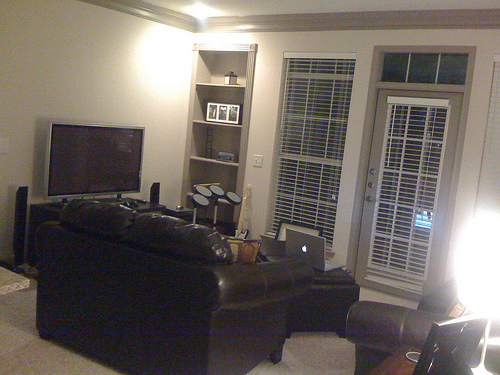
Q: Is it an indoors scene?
A: Yes, it is indoors.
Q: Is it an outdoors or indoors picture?
A: It is indoors.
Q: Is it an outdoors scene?
A: No, it is indoors.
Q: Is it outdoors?
A: No, it is indoors.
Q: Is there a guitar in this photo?
A: Yes, there is a guitar.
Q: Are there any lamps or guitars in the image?
A: Yes, there is a guitar.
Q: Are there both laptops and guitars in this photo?
A: Yes, there are both a guitar and a laptop.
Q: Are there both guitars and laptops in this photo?
A: Yes, there are both a guitar and a laptop.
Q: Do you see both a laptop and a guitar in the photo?
A: Yes, there are both a guitar and a laptop.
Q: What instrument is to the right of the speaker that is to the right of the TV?
A: The instrument is a guitar.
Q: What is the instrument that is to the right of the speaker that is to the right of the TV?
A: The instrument is a guitar.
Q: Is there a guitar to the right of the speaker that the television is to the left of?
A: Yes, there is a guitar to the right of the speaker.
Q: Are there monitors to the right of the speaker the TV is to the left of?
A: No, there is a guitar to the right of the speaker.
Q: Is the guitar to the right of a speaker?
A: Yes, the guitar is to the right of a speaker.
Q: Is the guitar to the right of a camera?
A: No, the guitar is to the right of a speaker.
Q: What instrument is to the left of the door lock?
A: The instrument is a guitar.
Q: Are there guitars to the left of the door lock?
A: Yes, there is a guitar to the left of the lock.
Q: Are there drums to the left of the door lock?
A: No, there is a guitar to the left of the lock.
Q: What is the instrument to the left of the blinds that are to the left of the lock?
A: The instrument is a guitar.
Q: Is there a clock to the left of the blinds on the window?
A: No, there is a guitar to the left of the blinds.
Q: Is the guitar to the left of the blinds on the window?
A: Yes, the guitar is to the left of the blinds.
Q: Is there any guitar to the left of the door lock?
A: Yes, there is a guitar to the left of the lock.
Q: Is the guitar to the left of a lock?
A: Yes, the guitar is to the left of a lock.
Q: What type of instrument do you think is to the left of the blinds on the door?
A: The instrument is a guitar.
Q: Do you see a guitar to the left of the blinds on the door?
A: Yes, there is a guitar to the left of the blinds.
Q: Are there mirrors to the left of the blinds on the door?
A: No, there is a guitar to the left of the blinds.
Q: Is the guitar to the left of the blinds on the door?
A: Yes, the guitar is to the left of the blinds.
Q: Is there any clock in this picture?
A: No, there are no clocks.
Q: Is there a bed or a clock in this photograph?
A: No, there are no clocks or beds.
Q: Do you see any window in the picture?
A: Yes, there are windows.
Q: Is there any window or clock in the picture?
A: Yes, there are windows.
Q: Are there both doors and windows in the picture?
A: Yes, there are both windows and a door.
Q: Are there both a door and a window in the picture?
A: Yes, there are both a window and a door.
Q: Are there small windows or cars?
A: Yes, there are small windows.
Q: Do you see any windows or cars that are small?
A: Yes, the windows are small.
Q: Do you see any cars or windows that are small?
A: Yes, the windows are small.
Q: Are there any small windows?
A: Yes, there are small windows.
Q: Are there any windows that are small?
A: Yes, there are windows that are small.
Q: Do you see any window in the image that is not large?
A: Yes, there are small windows.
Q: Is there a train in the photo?
A: No, there are no trains.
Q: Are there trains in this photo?
A: No, there are no trains.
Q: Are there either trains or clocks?
A: No, there are no trains or clocks.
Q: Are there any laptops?
A: Yes, there is a laptop.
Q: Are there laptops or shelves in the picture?
A: Yes, there is a laptop.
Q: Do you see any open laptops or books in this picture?
A: Yes, there is an open laptop.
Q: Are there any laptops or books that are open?
A: Yes, the laptop is open.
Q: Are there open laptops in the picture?
A: Yes, there is an open laptop.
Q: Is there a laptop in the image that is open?
A: Yes, there is a laptop that is open.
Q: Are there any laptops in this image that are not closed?
A: Yes, there is a open laptop.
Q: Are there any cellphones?
A: No, there are no cellphones.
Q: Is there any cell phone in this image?
A: No, there are no cell phones.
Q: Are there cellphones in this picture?
A: No, there are no cellphones.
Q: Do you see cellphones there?
A: No, there are no cellphones.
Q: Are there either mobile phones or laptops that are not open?
A: No, there is a laptop but it is open.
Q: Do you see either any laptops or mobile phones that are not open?
A: No, there is a laptop but it is open.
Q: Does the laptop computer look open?
A: Yes, the laptop computer is open.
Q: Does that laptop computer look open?
A: Yes, the laptop computer is open.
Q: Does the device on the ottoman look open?
A: Yes, the laptop computer is open.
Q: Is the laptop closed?
A: No, the laptop is open.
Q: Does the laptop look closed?
A: No, the laptop is open.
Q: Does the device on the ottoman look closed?
A: No, the laptop is open.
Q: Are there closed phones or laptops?
A: No, there is a laptop but it is open.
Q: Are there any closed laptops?
A: No, there is a laptop but it is open.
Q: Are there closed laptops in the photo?
A: No, there is a laptop but it is open.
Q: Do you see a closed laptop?
A: No, there is a laptop but it is open.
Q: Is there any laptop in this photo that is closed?
A: No, there is a laptop but it is open.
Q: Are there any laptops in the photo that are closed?
A: No, there is a laptop but it is open.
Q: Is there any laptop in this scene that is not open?
A: No, there is a laptop but it is open.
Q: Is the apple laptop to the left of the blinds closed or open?
A: The laptop is open.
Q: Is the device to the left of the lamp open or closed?
A: The laptop is open.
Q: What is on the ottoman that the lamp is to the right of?
A: The laptop is on the ottoman.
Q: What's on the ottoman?
A: The laptop is on the ottoman.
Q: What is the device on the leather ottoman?
A: The device is a laptop.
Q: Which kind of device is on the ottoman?
A: The device is a laptop.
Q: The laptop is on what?
A: The laptop is on the ottoman.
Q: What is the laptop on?
A: The laptop is on the ottoman.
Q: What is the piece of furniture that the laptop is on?
A: The piece of furniture is an ottoman.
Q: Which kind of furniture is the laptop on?
A: The laptop is on the ottoman.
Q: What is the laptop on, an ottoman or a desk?
A: The laptop is on an ottoman.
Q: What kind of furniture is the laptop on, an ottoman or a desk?
A: The laptop is on an ottoman.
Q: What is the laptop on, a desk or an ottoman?
A: The laptop is on an ottoman.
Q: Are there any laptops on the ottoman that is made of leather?
A: Yes, there is a laptop on the ottoman.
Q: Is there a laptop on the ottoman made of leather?
A: Yes, there is a laptop on the ottoman.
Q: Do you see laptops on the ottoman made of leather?
A: Yes, there is a laptop on the ottoman.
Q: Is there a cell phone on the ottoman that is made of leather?
A: No, there is a laptop on the ottoman.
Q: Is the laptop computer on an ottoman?
A: Yes, the laptop computer is on an ottoman.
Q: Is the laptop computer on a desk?
A: No, the laptop computer is on an ottoman.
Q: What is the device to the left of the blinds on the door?
A: The device is a laptop.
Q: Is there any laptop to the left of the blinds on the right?
A: Yes, there is a laptop to the left of the blinds.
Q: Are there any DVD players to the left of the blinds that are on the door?
A: No, there is a laptop to the left of the blinds.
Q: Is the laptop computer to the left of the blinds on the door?
A: Yes, the laptop computer is to the left of the blinds.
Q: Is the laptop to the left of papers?
A: No, the laptop is to the left of the blinds.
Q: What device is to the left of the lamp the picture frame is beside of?
A: The device is a laptop.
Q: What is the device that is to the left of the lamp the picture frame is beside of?
A: The device is a laptop.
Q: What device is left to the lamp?
A: The device is a laptop.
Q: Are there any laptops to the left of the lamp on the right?
A: Yes, there is a laptop to the left of the lamp.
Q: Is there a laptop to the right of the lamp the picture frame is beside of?
A: No, the laptop is to the left of the lamp.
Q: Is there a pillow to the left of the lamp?
A: No, there is a laptop to the left of the lamp.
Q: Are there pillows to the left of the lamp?
A: No, there is a laptop to the left of the lamp.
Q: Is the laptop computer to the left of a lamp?
A: Yes, the laptop computer is to the left of a lamp.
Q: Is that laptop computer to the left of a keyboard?
A: No, the laptop computer is to the left of a lamp.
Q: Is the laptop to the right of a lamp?
A: No, the laptop is to the left of a lamp.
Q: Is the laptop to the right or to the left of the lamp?
A: The laptop is to the left of the lamp.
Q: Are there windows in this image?
A: Yes, there is a window.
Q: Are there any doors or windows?
A: Yes, there is a window.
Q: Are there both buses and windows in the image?
A: No, there is a window but no buses.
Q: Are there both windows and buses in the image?
A: No, there is a window but no buses.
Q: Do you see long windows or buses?
A: Yes, there is a long window.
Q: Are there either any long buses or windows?
A: Yes, there is a long window.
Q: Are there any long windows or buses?
A: Yes, there is a long window.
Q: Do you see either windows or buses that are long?
A: Yes, the window is long.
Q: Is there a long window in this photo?
A: Yes, there is a long window.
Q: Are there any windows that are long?
A: Yes, there is a window that is long.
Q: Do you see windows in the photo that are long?
A: Yes, there is a window that is long.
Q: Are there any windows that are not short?
A: Yes, there is a long window.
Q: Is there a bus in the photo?
A: No, there are no buses.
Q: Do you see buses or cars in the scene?
A: No, there are no buses or cars.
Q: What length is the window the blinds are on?
A: The window is long.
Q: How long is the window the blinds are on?
A: The window is long.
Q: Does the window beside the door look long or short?
A: The window is long.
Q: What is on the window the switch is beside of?
A: The blinds are on the window.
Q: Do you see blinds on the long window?
A: Yes, there are blinds on the window.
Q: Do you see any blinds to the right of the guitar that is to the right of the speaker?
A: Yes, there are blinds to the right of the guitar.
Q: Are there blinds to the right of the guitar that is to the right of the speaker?
A: Yes, there are blinds to the right of the guitar.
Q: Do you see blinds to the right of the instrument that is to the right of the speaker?
A: Yes, there are blinds to the right of the guitar.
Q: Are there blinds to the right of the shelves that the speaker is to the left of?
A: Yes, there are blinds to the right of the shelves.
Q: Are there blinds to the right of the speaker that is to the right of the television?
A: Yes, there are blinds to the right of the speaker.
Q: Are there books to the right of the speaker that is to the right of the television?
A: No, there are blinds to the right of the speaker.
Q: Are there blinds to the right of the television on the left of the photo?
A: Yes, there are blinds to the right of the TV.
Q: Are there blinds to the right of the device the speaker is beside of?
A: Yes, there are blinds to the right of the TV.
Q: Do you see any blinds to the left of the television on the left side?
A: No, the blinds are to the right of the TV.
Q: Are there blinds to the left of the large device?
A: No, the blinds are to the right of the TV.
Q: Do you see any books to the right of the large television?
A: No, there are blinds to the right of the TV.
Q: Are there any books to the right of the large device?
A: No, there are blinds to the right of the TV.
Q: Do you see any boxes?
A: No, there are no boxes.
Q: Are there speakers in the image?
A: Yes, there is a speaker.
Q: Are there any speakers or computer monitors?
A: Yes, there is a speaker.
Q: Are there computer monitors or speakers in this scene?
A: Yes, there is a speaker.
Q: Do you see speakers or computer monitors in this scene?
A: Yes, there is a speaker.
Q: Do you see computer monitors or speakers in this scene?
A: Yes, there is a speaker.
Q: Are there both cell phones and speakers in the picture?
A: No, there is a speaker but no cell phones.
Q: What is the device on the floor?
A: The device is a speaker.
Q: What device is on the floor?
A: The device is a speaker.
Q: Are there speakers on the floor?
A: Yes, there is a speaker on the floor.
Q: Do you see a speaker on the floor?
A: Yes, there is a speaker on the floor.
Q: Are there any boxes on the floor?
A: No, there is a speaker on the floor.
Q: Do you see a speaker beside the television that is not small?
A: Yes, there is a speaker beside the television.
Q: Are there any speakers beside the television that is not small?
A: Yes, there is a speaker beside the television.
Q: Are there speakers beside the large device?
A: Yes, there is a speaker beside the television.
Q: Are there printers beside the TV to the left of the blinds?
A: No, there is a speaker beside the TV.